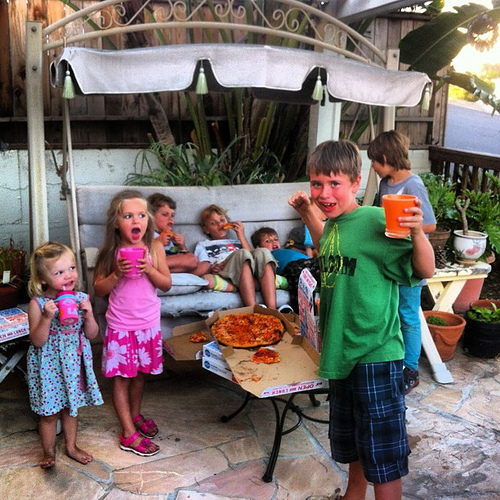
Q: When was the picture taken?
A: Daytime.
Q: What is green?
A: Boy's shirt.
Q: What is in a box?
A: Pizza.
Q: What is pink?
A: One girl's shirt.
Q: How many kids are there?
A: Seven.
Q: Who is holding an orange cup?
A: Boy in green.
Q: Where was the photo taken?
A: On a patio.